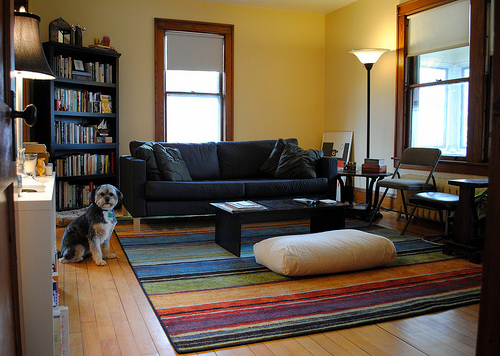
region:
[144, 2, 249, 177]
long wall mirror on wall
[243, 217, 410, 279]
big pillow on floor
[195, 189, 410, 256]
black center table in living room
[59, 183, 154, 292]
black and white dog sitting in living room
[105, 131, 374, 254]
black couch in living room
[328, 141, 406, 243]
side table in living room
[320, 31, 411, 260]
floor lamp in living room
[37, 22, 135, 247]
black book shelf in living room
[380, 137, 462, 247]
folding chair in living room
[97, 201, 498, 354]
colorful rug on floor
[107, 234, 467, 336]
a color striped rug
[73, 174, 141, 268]
a black and white dog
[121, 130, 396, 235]
a blue couch with pillows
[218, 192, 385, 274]
a black coffee table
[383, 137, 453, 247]
a folding chair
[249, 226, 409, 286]
a white dog bed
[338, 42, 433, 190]
a black and white lamp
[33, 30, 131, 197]
a black book case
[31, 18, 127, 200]
a black book case with books on it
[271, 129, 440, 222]
a table next to the blue couch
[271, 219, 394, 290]
Large white pillow on rug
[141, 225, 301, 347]
Colorful rug on floor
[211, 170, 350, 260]
Coffee table is black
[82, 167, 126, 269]
Dog sitting on wood floor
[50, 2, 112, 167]
Black bookshelf in corner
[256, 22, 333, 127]
Off white walls in room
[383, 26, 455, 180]
Windows have brown wood trim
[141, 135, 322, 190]
Black couch near wall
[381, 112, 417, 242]
Gray folding chair near window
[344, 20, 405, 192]
Tall black lamp near wall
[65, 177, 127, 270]
A house dog is staring at the camera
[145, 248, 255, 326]
An area rug with colorful lines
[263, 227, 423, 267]
A giant light color throw pillow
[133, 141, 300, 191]
A black leather long sofa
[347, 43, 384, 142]
A floor lamp is on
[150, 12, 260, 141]
A two-paneled window in a wood frame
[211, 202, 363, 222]
A dark and long coffee table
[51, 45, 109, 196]
A dark wood bookshelf with books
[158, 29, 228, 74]
A white window shade is lifted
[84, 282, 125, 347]
A light brown hardwood floor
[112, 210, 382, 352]
Multi-colored fashion rug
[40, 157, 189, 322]
Cute dog sitting on hardwood floor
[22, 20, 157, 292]
bookcase filled with interesting books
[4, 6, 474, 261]
living room area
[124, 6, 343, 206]
unadorned window with draw shade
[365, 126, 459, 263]
folding chair by window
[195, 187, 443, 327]
sitting pillow in front of coffee table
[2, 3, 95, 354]
bookcase along the wall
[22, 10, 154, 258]
bookcase in the corner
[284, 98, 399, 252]
modern art hidden behind couch